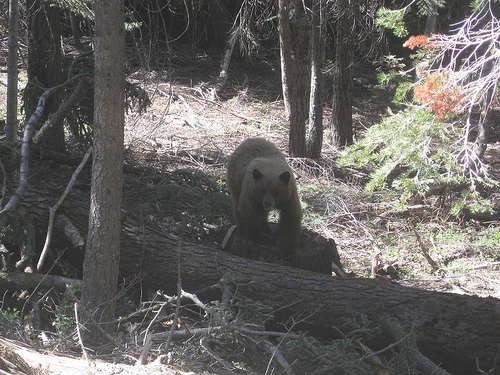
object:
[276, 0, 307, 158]
trunks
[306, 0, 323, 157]
trunks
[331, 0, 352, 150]
trunks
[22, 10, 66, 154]
trunks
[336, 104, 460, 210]
green leaves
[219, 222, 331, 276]
stump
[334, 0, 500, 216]
branch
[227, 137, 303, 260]
bear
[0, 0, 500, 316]
forest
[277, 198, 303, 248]
front legs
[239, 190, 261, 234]
front legs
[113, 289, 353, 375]
sticks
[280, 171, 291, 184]
ear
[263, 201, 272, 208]
nose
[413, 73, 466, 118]
leaves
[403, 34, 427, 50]
leaves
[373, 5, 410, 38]
leaves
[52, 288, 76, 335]
leaves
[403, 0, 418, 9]
branch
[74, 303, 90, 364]
branch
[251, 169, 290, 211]
head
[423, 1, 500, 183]
dead leaves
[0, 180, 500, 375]
log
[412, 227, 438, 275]
sticks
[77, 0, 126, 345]
trees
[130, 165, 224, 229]
grass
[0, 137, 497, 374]
ground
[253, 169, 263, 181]
ear